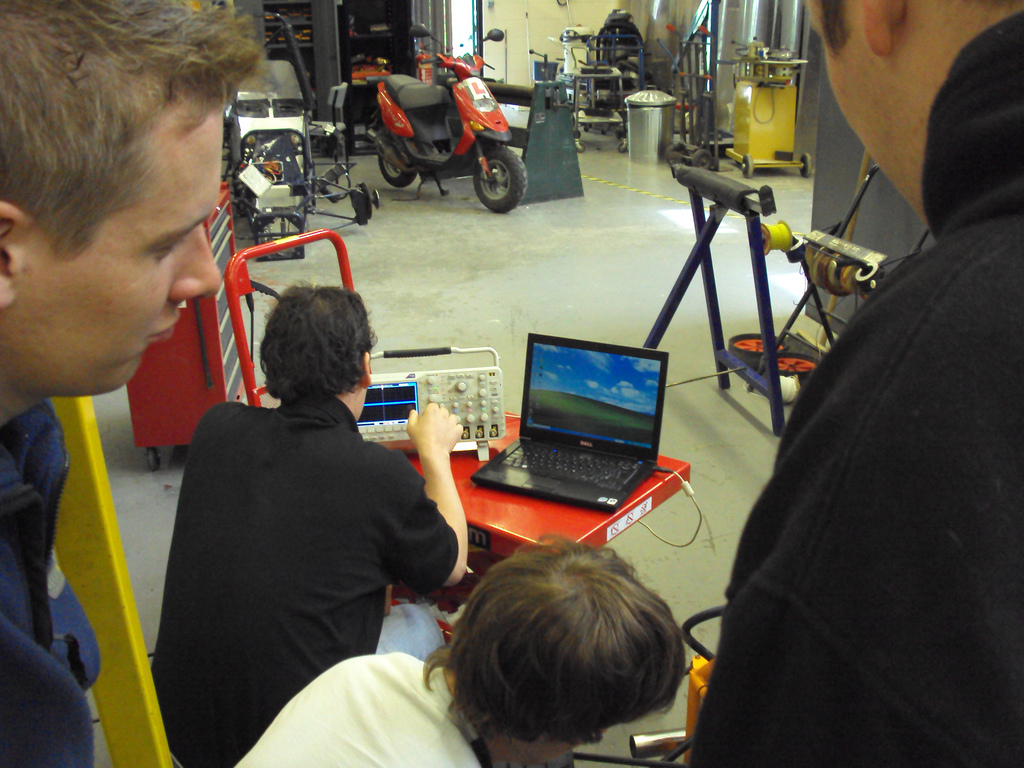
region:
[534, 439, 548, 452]
a key on a keyboard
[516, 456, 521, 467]
a key on a keyboard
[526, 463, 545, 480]
a key on a keyboard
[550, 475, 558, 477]
a key on a keyboard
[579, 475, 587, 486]
a key on a keyboard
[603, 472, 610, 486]
a key on a keyboard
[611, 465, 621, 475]
a key on a keyboard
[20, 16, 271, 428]
the head of a man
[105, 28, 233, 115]
the hair of a man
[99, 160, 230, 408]
the face of a man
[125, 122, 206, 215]
the forehead of a man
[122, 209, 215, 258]
the eyebrows of a man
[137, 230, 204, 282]
the eye of a man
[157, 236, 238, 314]
the nose of a man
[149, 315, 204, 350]
the lips of a man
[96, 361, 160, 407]
the chin of a man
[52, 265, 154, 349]
the cheeks of a man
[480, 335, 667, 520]
computer sitting on a red shelf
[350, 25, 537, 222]
red scooter sitting across the shop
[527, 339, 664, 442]
laptop screen has a landscape picture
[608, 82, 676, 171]
silver metal trashcan across the shop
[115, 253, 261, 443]
red rolling tool box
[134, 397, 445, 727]
man is wearing a black pullover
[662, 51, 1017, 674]
man is wearing a black jacket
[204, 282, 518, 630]
man is working on a machine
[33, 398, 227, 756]
yellow post behind the man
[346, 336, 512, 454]
automotive equipment in shop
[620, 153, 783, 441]
automotive equipment in shop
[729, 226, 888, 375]
automotive equipment in shop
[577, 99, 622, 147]
automotive equipment in shop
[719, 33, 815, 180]
automotive equipment in shop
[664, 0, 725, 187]
automotive equipment in shop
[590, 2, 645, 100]
automotive equipment in shop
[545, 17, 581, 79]
automotive equipment in shop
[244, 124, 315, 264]
automotive equipment in shop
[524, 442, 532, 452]
keyboard has a key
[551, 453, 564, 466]
keyboard has a key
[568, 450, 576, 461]
keyboard has a key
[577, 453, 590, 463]
keyboard has a key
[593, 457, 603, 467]
keyboard has a key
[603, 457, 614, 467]
keyboard has a key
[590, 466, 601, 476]
keyboard has a key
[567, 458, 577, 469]
keyboard has a key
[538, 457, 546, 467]
keyboard has a key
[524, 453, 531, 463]
keyboard has a key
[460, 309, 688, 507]
black laptop on red pallet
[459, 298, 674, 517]
black laptop on red pallet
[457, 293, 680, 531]
black laptop on red pallet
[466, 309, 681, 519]
black laptop on red pallet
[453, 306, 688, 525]
black laptop on red pallet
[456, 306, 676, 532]
black laptop on red pallet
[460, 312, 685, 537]
black laptop on red pallet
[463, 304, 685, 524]
black laptop on red pallet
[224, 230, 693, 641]
orange dollie sitting in a warehouse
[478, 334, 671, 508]
black laptop sitting on the dollie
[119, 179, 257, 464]
tall, orange tool box sitting in warehouse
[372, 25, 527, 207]
red and black moped sitting in warehouse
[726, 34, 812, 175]
yellow chemical cart sitting in warehouse